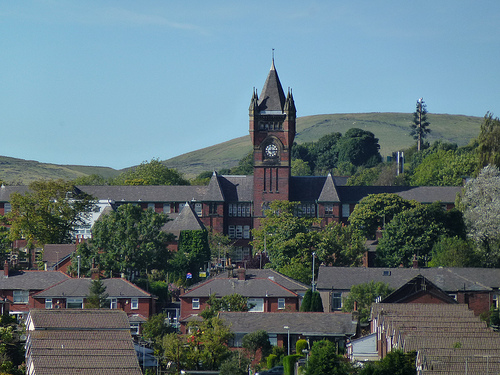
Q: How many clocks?
A: One.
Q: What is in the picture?
A: Buildings.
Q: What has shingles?
A: The roofs.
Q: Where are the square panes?
A: In the windows.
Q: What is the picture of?
A: A neighborhood.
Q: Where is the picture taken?
A: Village.